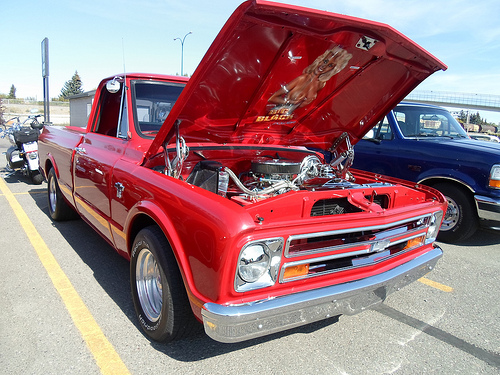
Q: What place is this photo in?
A: It is at the parking lot.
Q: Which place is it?
A: It is a parking lot.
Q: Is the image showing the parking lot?
A: Yes, it is showing the parking lot.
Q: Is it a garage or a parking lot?
A: It is a parking lot.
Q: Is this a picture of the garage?
A: No, the picture is showing the parking lot.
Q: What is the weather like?
A: It is cloudy.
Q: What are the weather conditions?
A: It is cloudy.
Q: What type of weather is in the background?
A: It is cloudy.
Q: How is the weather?
A: It is cloudy.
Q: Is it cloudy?
A: Yes, it is cloudy.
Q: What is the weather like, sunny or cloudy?
A: It is cloudy.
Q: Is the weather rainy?
A: No, it is cloudy.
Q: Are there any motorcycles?
A: Yes, there is a motorcycle.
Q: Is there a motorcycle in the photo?
A: Yes, there is a motorcycle.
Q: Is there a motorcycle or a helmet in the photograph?
A: Yes, there is a motorcycle.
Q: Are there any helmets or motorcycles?
A: Yes, there is a motorcycle.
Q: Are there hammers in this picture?
A: No, there are no hammers.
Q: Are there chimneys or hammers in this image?
A: No, there are no hammers or chimneys.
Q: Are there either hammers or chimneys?
A: No, there are no hammers or chimneys.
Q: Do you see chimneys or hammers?
A: No, there are no hammers or chimneys.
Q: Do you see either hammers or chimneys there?
A: No, there are no hammers or chimneys.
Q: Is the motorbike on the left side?
A: Yes, the motorbike is on the left of the image.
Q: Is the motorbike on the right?
A: No, the motorbike is on the left of the image.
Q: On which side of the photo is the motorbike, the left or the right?
A: The motorbike is on the left of the image.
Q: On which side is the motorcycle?
A: The motorcycle is on the left of the image.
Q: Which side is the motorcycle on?
A: The motorcycle is on the left of the image.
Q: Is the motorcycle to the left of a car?
A: Yes, the motorcycle is to the left of a car.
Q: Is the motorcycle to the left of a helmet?
A: No, the motorcycle is to the left of a car.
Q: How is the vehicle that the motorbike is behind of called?
A: The vehicle is a car.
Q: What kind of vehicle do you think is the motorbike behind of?
A: The motorbike is behind the car.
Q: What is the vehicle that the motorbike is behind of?
A: The vehicle is a car.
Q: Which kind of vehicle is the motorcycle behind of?
A: The motorbike is behind the car.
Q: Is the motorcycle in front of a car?
A: No, the motorcycle is behind a car.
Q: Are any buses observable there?
A: No, there are no buses.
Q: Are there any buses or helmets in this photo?
A: No, there are no buses or helmets.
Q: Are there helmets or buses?
A: No, there are no buses or helmets.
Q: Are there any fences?
A: No, there are no fences.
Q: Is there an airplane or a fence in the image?
A: No, there are no fences or airplanes.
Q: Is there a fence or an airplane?
A: No, there are no fences or airplanes.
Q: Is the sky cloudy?
A: Yes, the sky is cloudy.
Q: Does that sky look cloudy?
A: Yes, the sky is cloudy.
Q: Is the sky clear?
A: No, the sky is cloudy.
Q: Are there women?
A: Yes, there is a woman.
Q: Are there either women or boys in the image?
A: Yes, there is a woman.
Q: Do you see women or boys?
A: Yes, there is a woman.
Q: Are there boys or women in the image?
A: Yes, there is a woman.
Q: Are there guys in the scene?
A: No, there are no guys.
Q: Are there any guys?
A: No, there are no guys.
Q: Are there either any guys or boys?
A: No, there are no guys or boys.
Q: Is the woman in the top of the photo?
A: Yes, the woman is in the top of the image.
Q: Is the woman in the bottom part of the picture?
A: No, the woman is in the top of the image.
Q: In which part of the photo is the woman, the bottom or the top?
A: The woman is in the top of the image.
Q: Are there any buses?
A: No, there are no buses.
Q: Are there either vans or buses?
A: No, there are no buses or vans.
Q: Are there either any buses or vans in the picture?
A: No, there are no buses or vans.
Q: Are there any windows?
A: Yes, there is a window.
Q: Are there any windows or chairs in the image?
A: Yes, there is a window.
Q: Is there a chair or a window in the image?
A: Yes, there is a window.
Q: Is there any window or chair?
A: Yes, there is a window.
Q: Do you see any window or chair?
A: Yes, there is a window.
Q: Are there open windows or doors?
A: Yes, there is an open window.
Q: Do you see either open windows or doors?
A: Yes, there is an open window.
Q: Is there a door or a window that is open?
A: Yes, the window is open.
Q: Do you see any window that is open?
A: Yes, there is an open window.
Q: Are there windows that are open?
A: Yes, there is a window that is open.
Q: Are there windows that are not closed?
A: Yes, there is a open window.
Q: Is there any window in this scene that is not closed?
A: Yes, there is a open window.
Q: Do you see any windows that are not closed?
A: Yes, there is a open window.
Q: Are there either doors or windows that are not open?
A: No, there is a window but it is open.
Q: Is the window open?
A: Yes, the window is open.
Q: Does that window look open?
A: Yes, the window is open.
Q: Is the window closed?
A: No, the window is open.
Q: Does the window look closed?
A: No, the window is open.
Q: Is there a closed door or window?
A: No, there is a window but it is open.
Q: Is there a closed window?
A: No, there is a window but it is open.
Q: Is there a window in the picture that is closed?
A: No, there is a window but it is open.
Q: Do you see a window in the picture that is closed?
A: No, there is a window but it is open.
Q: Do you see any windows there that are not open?
A: No, there is a window but it is open.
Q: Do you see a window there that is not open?
A: No, there is a window but it is open.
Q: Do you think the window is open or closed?
A: The window is open.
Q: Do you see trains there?
A: No, there are no trains.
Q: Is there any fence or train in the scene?
A: No, there are no trains or fences.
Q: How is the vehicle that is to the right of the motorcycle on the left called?
A: The vehicle is a car.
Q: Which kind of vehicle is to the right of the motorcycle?
A: The vehicle is a car.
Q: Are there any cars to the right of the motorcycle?
A: Yes, there is a car to the right of the motorcycle.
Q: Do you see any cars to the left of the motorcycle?
A: No, the car is to the right of the motorcycle.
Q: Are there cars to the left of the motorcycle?
A: No, the car is to the right of the motorcycle.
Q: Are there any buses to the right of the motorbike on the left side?
A: No, there is a car to the right of the motorbike.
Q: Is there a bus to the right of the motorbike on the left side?
A: No, there is a car to the right of the motorbike.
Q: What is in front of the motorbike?
A: The car is in front of the motorbike.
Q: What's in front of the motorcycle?
A: The car is in front of the motorbike.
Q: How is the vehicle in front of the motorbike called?
A: The vehicle is a car.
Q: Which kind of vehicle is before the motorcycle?
A: The vehicle is a car.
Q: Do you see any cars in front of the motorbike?
A: Yes, there is a car in front of the motorbike.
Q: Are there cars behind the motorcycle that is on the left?
A: No, the car is in front of the motorcycle.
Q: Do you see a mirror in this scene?
A: Yes, there is a mirror.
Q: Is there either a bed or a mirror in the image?
A: Yes, there is a mirror.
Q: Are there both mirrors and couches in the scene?
A: No, there is a mirror but no couches.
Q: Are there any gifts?
A: No, there are no gifts.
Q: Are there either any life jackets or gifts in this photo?
A: No, there are no gifts or life jackets.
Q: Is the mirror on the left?
A: Yes, the mirror is on the left of the image.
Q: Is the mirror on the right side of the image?
A: No, the mirror is on the left of the image.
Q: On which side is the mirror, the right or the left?
A: The mirror is on the left of the image.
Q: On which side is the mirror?
A: The mirror is on the left of the image.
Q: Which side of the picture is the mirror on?
A: The mirror is on the left of the image.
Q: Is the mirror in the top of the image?
A: Yes, the mirror is in the top of the image.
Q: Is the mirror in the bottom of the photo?
A: No, the mirror is in the top of the image.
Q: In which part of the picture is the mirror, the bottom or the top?
A: The mirror is in the top of the image.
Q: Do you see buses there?
A: No, there are no buses.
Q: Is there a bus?
A: No, there are no buses.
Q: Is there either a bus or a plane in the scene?
A: No, there are no buses or airplanes.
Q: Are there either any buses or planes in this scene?
A: No, there are no buses or planes.